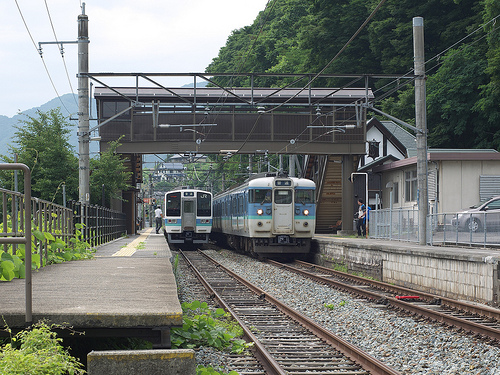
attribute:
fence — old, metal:
[4, 161, 141, 258]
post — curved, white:
[349, 170, 369, 231]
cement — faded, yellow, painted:
[85, 346, 195, 373]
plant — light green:
[1, 322, 83, 372]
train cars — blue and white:
[162, 175, 317, 256]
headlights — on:
[258, 209, 310, 216]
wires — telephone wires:
[15, 0, 80, 118]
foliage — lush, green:
[206, 0, 498, 148]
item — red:
[388, 281, 418, 319]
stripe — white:
[107, 223, 159, 267]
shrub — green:
[186, 278, 243, 359]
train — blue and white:
[240, 168, 344, 258]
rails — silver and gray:
[14, 188, 88, 262]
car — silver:
[424, 168, 499, 252]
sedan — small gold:
[443, 198, 487, 236]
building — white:
[359, 111, 435, 235]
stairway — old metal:
[318, 124, 359, 224]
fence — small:
[401, 190, 481, 282]